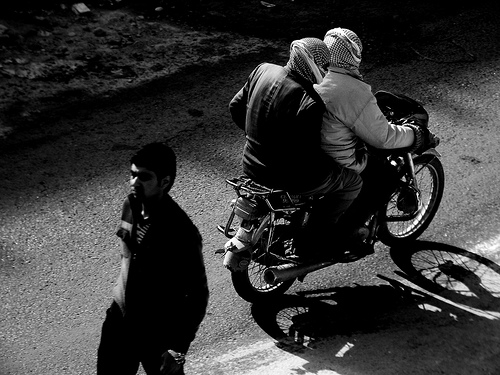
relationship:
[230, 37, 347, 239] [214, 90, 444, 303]
person on motorcycle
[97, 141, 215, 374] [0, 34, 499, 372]
man walking on road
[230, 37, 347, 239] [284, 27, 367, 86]
person wearing headcovering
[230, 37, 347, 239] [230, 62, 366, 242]
person wearing clothes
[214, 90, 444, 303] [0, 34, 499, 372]
motorcycle on road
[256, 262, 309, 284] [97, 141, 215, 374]
pipe pointed at man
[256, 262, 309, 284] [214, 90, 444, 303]
pipe on motorcycle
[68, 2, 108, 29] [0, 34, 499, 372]
debris on road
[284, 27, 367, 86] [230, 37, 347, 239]
headcovering on person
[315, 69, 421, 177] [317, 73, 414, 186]
driver wears jacket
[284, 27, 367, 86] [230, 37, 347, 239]
hoods on person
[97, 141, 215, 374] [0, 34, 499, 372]
man on road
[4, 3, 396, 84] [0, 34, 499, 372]
dirt by road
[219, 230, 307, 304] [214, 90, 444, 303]
wheel on motorcycle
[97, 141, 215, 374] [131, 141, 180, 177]
man with hair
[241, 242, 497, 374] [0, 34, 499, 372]
shadow on road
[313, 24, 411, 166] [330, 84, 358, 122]
person wearing white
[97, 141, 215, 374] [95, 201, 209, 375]
man wear suit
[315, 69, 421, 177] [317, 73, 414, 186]
cyclist wearing jacket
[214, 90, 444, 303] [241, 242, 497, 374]
motorcycle has shadow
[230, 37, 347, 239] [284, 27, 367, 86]
person have headcovering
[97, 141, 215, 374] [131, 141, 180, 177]
man has hair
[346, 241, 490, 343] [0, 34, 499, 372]
line in road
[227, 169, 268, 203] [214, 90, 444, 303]
rack on bike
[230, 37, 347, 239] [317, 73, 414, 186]
person wearing jacket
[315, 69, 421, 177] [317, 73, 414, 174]
driver wearing a jacket